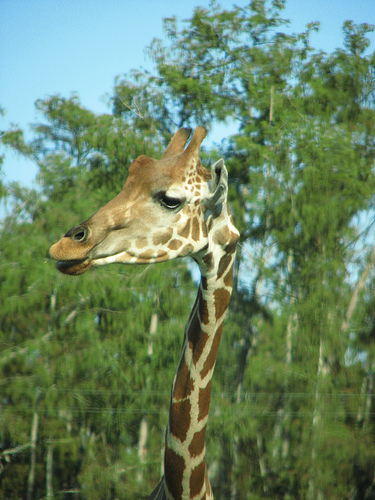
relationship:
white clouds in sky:
[5, 36, 34, 56] [0, 0, 374, 318]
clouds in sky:
[3, 5, 185, 97] [2, 2, 374, 187]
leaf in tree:
[337, 101, 354, 123] [226, 17, 372, 498]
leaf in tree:
[306, 171, 319, 178] [226, 17, 372, 498]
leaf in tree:
[297, 90, 305, 104] [226, 17, 372, 498]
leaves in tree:
[273, 351, 309, 389] [206, 43, 373, 398]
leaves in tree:
[79, 325, 126, 365] [1, 2, 372, 495]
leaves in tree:
[0, 2, 373, 499] [1, 2, 372, 495]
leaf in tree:
[23, 351, 35, 363] [1, 75, 217, 498]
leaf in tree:
[119, 303, 131, 321] [1, 75, 217, 498]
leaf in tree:
[119, 342, 131, 354] [1, 75, 217, 498]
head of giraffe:
[47, 121, 249, 279] [79, 154, 253, 431]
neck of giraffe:
[162, 249, 236, 499] [23, 95, 326, 489]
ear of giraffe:
[206, 156, 230, 215] [38, 114, 245, 498]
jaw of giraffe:
[47, 235, 93, 278] [38, 114, 245, 498]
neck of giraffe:
[162, 249, 236, 499] [38, 114, 245, 498]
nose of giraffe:
[61, 228, 92, 240] [133, 156, 238, 485]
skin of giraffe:
[189, 337, 206, 444] [24, 43, 335, 475]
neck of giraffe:
[163, 257, 234, 499] [38, 114, 245, 498]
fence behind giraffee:
[7, 379, 372, 413] [64, 124, 238, 498]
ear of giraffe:
[209, 156, 230, 212] [22, 137, 330, 362]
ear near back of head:
[209, 156, 230, 212] [47, 121, 249, 279]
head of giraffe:
[47, 121, 249, 279] [22, 137, 330, 362]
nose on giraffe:
[61, 222, 88, 243] [42, 116, 269, 290]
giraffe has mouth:
[71, 129, 255, 477] [51, 248, 99, 274]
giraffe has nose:
[71, 129, 255, 477] [52, 218, 93, 243]